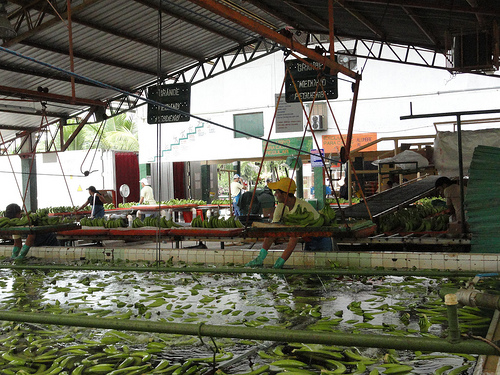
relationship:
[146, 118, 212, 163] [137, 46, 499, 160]
line on wall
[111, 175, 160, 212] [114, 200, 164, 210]
scale near vegetables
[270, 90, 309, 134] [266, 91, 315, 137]
sign on wall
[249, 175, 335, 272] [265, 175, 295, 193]
man wearing hat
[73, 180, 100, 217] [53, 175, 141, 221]
person in background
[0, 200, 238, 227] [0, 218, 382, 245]
bananas are on tables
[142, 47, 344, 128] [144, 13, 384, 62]
signs are suspended from roof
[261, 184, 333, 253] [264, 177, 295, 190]
person has on hat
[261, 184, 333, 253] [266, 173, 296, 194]
person has on hat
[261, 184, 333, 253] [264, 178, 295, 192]
person has on cap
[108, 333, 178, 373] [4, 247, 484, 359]
fish in water tank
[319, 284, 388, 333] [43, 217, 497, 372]
fish in tank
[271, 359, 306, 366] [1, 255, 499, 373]
green fish in water tank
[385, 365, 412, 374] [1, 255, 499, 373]
green fish in water tank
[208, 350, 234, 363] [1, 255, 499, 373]
green fish in water tank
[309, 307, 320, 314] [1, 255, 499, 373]
green fish in water tank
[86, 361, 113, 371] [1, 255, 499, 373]
green fish in water tank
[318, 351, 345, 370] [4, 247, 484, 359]
fish in water tank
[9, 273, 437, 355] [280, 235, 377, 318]
green fish in tank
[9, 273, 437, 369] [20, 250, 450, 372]
green fish in water tank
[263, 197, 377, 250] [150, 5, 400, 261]
bananas on a scale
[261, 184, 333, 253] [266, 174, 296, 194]
person has a cap